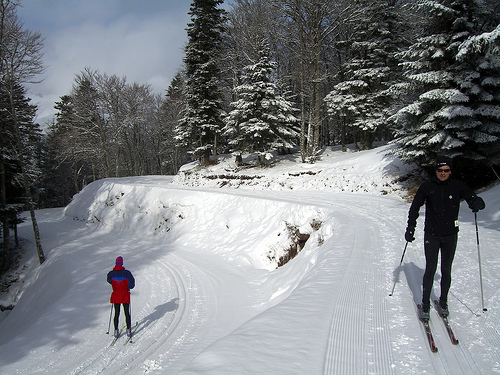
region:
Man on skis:
[415, 297, 464, 354]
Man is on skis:
[414, 297, 459, 354]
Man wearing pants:
[415, 227, 462, 309]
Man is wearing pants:
[419, 225, 461, 313]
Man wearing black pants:
[420, 232, 464, 317]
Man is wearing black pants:
[419, 232, 461, 308]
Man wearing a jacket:
[408, 177, 474, 236]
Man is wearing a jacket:
[405, 175, 477, 235]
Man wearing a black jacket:
[407, 181, 475, 240]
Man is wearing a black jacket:
[402, 176, 482, 238]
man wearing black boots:
[386, 159, 490, 354]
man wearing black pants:
[389, 159, 487, 356]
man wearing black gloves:
[393, 163, 485, 352]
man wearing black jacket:
[379, 160, 489, 355]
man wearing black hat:
[402, 164, 492, 344]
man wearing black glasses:
[396, 158, 486, 354]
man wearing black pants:
[103, 258, 138, 351]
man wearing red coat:
[101, 257, 139, 347]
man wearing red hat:
[102, 257, 136, 340]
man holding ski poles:
[394, 166, 489, 353]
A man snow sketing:
[81, 245, 145, 344]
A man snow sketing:
[405, 155, 485, 334]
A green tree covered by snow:
[236, 55, 300, 176]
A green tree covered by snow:
[176, 4, 223, 154]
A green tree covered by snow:
[327, 9, 400, 141]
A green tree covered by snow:
[415, 12, 498, 146]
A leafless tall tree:
[80, 82, 129, 178]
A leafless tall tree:
[108, 63, 159, 171]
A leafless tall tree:
[285, 4, 332, 155]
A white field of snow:
[179, 241, 293, 348]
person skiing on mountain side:
[411, 141, 469, 341]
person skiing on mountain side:
[119, 244, 149, 349]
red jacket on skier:
[109, 270, 131, 307]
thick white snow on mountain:
[298, 311, 375, 363]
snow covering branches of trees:
[391, 70, 451, 141]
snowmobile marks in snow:
[284, 250, 384, 372]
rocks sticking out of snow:
[263, 218, 335, 271]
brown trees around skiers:
[25, 75, 170, 171]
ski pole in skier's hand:
[375, 234, 414, 301]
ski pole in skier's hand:
[469, 225, 498, 315]